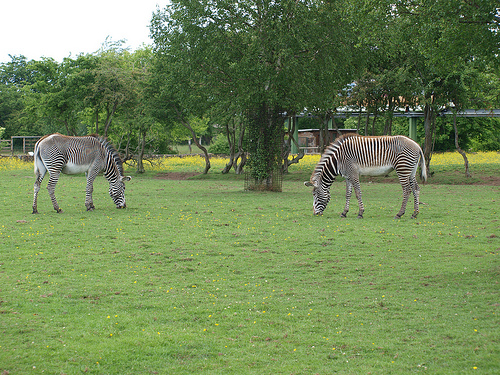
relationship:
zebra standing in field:
[302, 129, 424, 223] [0, 168, 497, 373]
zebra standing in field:
[30, 130, 131, 214] [0, 168, 497, 373]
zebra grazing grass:
[30, 130, 131, 214] [1, 146, 496, 373]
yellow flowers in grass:
[145, 149, 256, 178] [62, 231, 439, 368]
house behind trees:
[265, 100, 347, 155] [195, 19, 298, 194]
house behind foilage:
[265, 100, 347, 155] [244, 171, 283, 191]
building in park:
[293, 113, 330, 154] [0, 2, 497, 372]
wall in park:
[229, 203, 311, 221] [22, 25, 486, 372]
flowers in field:
[470, 365, 476, 372] [0, 168, 497, 373]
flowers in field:
[475, 324, 479, 336] [0, 168, 497, 373]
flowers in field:
[418, 362, 430, 370] [0, 168, 497, 373]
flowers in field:
[286, 342, 303, 352] [0, 168, 497, 373]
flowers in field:
[376, 287, 383, 299] [0, 168, 497, 373]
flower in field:
[208, 277, 215, 282] [0, 168, 497, 373]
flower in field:
[195, 251, 199, 257] [0, 168, 497, 373]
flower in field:
[189, 254, 194, 257] [0, 168, 497, 373]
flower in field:
[200, 279, 205, 284] [0, 168, 497, 373]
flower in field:
[180, 285, 185, 290] [0, 168, 497, 373]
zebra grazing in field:
[302, 132, 428, 219] [25, 234, 498, 345]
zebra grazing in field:
[32, 132, 132, 214] [25, 234, 498, 345]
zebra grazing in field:
[302, 132, 428, 219] [49, 306, 473, 367]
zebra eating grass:
[302, 132, 428, 219] [20, 234, 495, 357]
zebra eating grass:
[302, 132, 428, 219] [29, 281, 450, 367]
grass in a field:
[29, 281, 450, 367] [149, 159, 244, 183]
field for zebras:
[0, 224, 499, 374] [303, 132, 429, 218]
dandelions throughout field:
[2, 148, 499, 171] [33, 293, 472, 360]